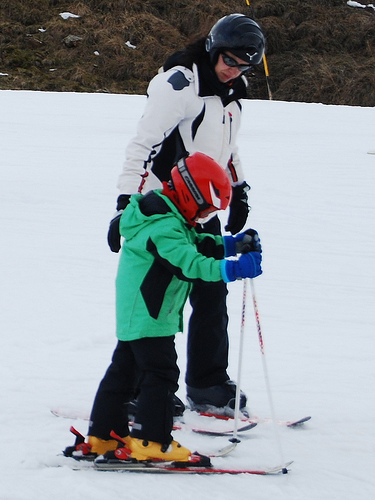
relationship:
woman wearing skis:
[109, 10, 265, 414] [51, 385, 310, 442]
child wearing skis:
[87, 151, 264, 462] [47, 443, 296, 477]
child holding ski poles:
[87, 151, 264, 462] [229, 245, 289, 480]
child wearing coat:
[87, 151, 264, 462] [110, 188, 224, 343]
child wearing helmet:
[87, 151, 264, 462] [170, 149, 233, 227]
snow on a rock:
[54, 6, 79, 24] [60, 32, 84, 50]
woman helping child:
[109, 10, 265, 414] [87, 151, 264, 462]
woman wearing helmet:
[109, 10, 265, 414] [205, 11, 265, 70]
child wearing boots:
[87, 151, 264, 462] [87, 426, 195, 465]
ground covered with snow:
[0, 84, 373, 499] [0, 88, 373, 500]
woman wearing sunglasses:
[109, 10, 265, 414] [219, 50, 251, 73]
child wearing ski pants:
[87, 151, 264, 462] [85, 332, 181, 442]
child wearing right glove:
[87, 151, 264, 462] [222, 251, 262, 282]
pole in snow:
[246, 0, 275, 103] [0, 88, 373, 500]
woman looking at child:
[109, 10, 265, 414] [87, 151, 264, 462]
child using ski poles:
[87, 151, 264, 462] [229, 245, 289, 480]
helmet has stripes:
[170, 149, 233, 227] [176, 156, 207, 209]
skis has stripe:
[89, 443, 296, 477] [154, 463, 265, 475]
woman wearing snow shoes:
[109, 10, 265, 414] [122, 378, 247, 419]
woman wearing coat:
[109, 10, 265, 414] [114, 38, 249, 227]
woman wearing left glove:
[109, 10, 265, 414] [221, 173, 251, 237]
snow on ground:
[54, 6, 79, 24] [1, 1, 374, 106]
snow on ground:
[121, 38, 137, 52] [1, 1, 374, 106]